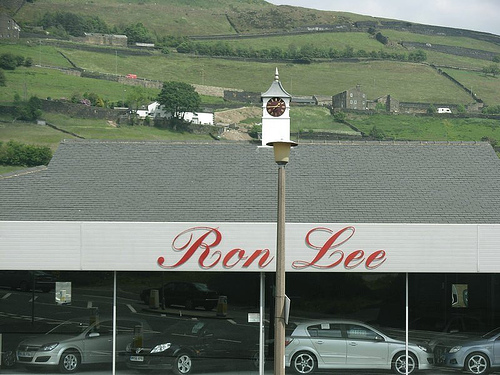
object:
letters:
[155, 225, 389, 276]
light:
[264, 141, 299, 169]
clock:
[265, 98, 288, 119]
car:
[281, 320, 436, 375]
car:
[12, 313, 138, 375]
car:
[121, 318, 268, 374]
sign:
[281, 291, 292, 326]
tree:
[151, 75, 204, 128]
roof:
[2, 138, 499, 221]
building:
[0, 138, 499, 368]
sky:
[265, 0, 498, 27]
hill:
[8, 2, 499, 106]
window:
[304, 320, 345, 343]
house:
[129, 97, 218, 128]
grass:
[3, 4, 499, 148]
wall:
[184, 113, 212, 124]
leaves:
[155, 79, 207, 113]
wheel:
[289, 347, 319, 374]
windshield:
[366, 319, 397, 339]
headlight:
[38, 342, 59, 351]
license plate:
[125, 354, 146, 364]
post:
[272, 161, 288, 374]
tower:
[257, 61, 291, 148]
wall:
[120, 223, 380, 274]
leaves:
[0, 137, 54, 168]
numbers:
[268, 97, 276, 105]